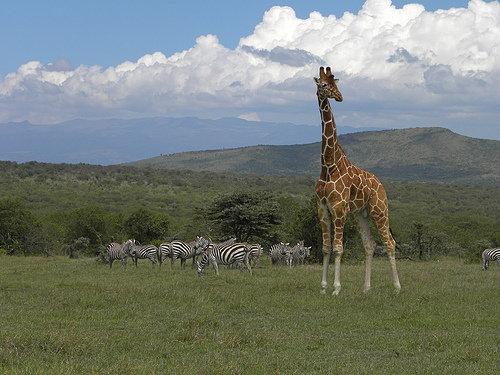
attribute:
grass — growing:
[176, 327, 386, 366]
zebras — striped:
[102, 238, 311, 277]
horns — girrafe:
[305, 63, 350, 113]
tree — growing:
[219, 192, 316, 251]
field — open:
[78, 284, 279, 346]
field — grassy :
[42, 248, 454, 372]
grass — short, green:
[68, 267, 350, 365]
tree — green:
[8, 207, 51, 259]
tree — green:
[68, 209, 112, 256]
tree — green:
[132, 209, 172, 244]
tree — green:
[192, 189, 284, 246]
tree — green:
[287, 199, 318, 253]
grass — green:
[92, 291, 270, 344]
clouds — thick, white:
[11, 11, 498, 88]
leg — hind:
[351, 218, 376, 293]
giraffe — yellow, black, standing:
[313, 66, 401, 294]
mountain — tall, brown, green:
[101, 125, 498, 185]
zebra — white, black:
[181, 223, 286, 288]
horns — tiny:
[317, 65, 333, 76]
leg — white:
[322, 232, 329, 267]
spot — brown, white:
[340, 173, 351, 187]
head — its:
[297, 47, 388, 144]